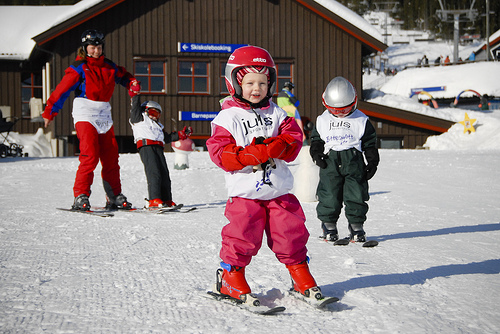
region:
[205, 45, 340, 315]
child on skis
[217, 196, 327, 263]
child wearing red snow pants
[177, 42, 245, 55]
blue sign on building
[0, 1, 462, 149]
brown building behind child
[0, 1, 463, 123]
snow on roof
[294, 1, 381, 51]
orange stripe along roof line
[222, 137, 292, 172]
child wearing bit red mittens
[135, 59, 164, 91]
windows on building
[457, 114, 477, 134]
yellow star in the snow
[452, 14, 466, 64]
gray metal pole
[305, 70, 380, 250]
Young skier in green suit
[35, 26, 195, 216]
Mother and child skier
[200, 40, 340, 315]
Child skier in bright pink suit with helmet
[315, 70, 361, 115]
Silver skiing helmet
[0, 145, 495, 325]
Field of snow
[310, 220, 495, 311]
Shadows on the snow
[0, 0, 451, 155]
Brown colored ski lodge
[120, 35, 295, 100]
Windows with a sign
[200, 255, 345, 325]
Ski boots and skis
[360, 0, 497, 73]
Ski lift and people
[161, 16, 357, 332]
a girl wearing snow shoes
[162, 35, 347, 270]
a young girl wearing snow shoes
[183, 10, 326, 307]
a young girl wearing a helmet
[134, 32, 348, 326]
a young girl wearing pink pants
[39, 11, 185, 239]
an adult helping a child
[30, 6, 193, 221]
a women helping a child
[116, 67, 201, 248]
a child falling on the snow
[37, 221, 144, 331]
white snow on the ground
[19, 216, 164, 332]
ground covered in snow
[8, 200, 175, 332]
ground cover in white snow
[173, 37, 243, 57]
a blue directional sign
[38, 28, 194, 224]
an adult holding up a child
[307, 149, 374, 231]
a pair of green snow pants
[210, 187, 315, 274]
a pair of pink snow pants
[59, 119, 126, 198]
a pair of red snow pants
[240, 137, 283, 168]
a pair of red winter gloves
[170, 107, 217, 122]
a blue directional sign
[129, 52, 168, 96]
a red framed window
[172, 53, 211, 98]
a red framed window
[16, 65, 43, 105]
a red framed window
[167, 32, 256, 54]
sign is blue and white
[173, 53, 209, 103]
four panes in the window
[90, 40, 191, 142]
woman holding kid's hand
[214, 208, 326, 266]
snow pants are pink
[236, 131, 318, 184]
ski gloves are red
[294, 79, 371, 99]
top of helmet is silver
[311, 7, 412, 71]
red stripe on the building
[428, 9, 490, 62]
pole for the ski lift